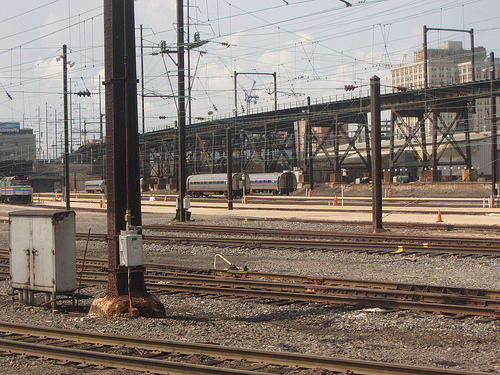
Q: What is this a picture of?
A: Train tracks.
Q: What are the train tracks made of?
A: Steel.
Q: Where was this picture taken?
A: At a railyard.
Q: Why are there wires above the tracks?
A: To power the trains.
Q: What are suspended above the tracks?
A: Wires.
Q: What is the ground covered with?
A: Gravel.